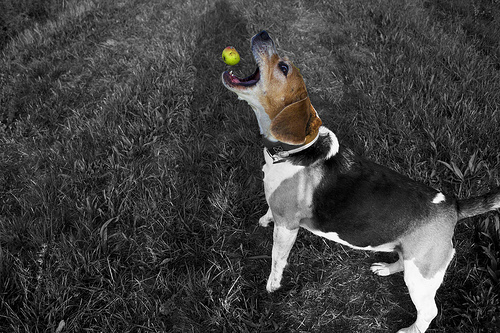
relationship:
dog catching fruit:
[219, 29, 499, 332] [221, 42, 244, 70]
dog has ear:
[219, 29, 499, 332] [257, 97, 314, 152]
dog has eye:
[219, 29, 499, 332] [275, 61, 293, 82]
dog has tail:
[219, 29, 499, 332] [457, 191, 498, 226]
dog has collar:
[219, 29, 499, 332] [263, 133, 322, 165]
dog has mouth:
[219, 29, 499, 332] [223, 41, 261, 91]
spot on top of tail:
[430, 190, 450, 211] [457, 191, 498, 226]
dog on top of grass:
[219, 29, 499, 332] [3, 1, 499, 332]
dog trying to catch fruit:
[219, 29, 499, 332] [221, 42, 244, 70]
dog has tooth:
[219, 29, 499, 332] [229, 67, 236, 79]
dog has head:
[219, 29, 499, 332] [216, 26, 321, 147]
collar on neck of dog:
[263, 133, 322, 165] [219, 29, 499, 332]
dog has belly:
[219, 29, 499, 332] [301, 196, 402, 255]